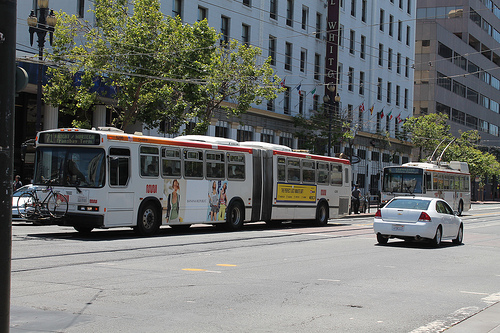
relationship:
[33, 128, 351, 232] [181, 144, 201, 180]
bus with a window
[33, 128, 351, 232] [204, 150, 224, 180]
bus with a window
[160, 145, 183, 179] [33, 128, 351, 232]
window on bus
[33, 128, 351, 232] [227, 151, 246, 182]
bus with a window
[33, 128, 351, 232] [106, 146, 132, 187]
bus on window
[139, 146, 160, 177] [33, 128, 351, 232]
window on bus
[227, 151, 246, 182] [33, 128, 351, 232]
window on bus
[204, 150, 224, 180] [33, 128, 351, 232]
window on bus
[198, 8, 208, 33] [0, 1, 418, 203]
glass on building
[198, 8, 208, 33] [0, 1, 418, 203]
glass in building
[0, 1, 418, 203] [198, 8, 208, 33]
building with glass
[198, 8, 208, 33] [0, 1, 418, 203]
glass in white building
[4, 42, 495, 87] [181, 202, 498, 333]
wire across street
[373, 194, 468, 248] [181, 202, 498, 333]
car on street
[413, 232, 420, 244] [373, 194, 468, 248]
exhaust on car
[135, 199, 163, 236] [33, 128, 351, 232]
wheel on bus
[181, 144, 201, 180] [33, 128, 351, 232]
window on white bus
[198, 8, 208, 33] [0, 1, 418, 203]
glass on white building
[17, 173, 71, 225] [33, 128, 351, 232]
bike on bus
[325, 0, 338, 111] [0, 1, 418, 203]
sign on building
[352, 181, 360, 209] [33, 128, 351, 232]
person with bus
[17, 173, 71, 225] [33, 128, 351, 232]
bike with bus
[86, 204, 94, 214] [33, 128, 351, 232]
light with bus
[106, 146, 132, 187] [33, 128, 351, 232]
window on bus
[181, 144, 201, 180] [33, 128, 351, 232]
window on bus